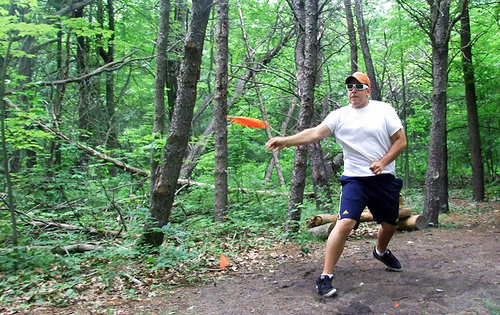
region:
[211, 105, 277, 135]
small orange Frisbee in the air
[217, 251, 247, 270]
orange flag on the ground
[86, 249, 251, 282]
gold leaves on the ground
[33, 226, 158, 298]
cluster of small green leaves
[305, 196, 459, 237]
selection of wooden logs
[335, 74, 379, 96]
sun glasses on man's face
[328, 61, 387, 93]
orange cap on man's head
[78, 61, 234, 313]
large black tree trunk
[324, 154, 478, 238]
man wearing blue shorts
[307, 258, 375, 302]
black and white sneakers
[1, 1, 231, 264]
a forest filled with lots of trees and plants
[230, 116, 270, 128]
orange frisbee in the air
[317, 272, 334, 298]
black shoe and white sock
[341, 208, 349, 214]
white logo on pants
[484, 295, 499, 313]
greenery grown on the ground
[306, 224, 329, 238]
log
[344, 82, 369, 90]
white glasses over the man's eyes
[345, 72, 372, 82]
orange baseball cap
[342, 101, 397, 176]
white t-shirt on the man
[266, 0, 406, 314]
man in the forest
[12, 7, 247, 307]
A forest with lots of foliage.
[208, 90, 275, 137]
An orange Frisbee flying through the air.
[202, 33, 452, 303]
A man throwing an orange Frisbee.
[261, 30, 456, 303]
A man standing in the forest.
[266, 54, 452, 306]
A man with an orange hat.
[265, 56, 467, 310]
Man standing on a dirt road.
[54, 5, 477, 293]
A tree lined dirt road.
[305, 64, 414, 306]
A man wearing white sunglasses.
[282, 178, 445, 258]
Stacked logs behind a man playing Frisbee.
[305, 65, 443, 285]
A man wearing blue shorts.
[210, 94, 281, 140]
orange frisbee.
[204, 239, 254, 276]
orange object laying on the ground.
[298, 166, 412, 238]
man wearing blue shorts.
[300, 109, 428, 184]
man wearing a white t shirt.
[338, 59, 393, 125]
human head wearing sun glasses and hat.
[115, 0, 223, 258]
Large tree trunk.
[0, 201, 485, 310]
Dirty road in a forest.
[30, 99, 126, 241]
green plants in a forest.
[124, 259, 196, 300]
leaves scattered on the ground.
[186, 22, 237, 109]
tree trunks in a forest.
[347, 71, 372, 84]
orange hat on man's head.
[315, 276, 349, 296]
black tennis shoe on man's foot.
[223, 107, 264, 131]
orange frisbee in the air.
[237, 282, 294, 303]
dirt path on the ground.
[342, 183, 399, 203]
blue shorts on man's waist.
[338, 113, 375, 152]
white shirt on man's torso.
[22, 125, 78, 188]
green leaves on trees.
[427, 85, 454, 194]
tree trunk behind man.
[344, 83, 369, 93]
sunglasses on man's face.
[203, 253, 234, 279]
orange flag on the ground.